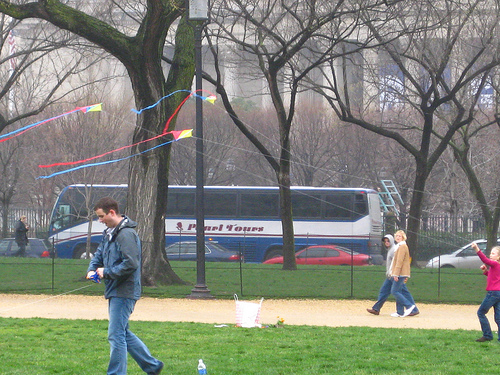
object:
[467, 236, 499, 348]
girl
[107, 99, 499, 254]
kite string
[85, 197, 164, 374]
man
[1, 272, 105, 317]
string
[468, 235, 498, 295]
pink shirt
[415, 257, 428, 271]
curb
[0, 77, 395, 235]
kite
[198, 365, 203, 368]
label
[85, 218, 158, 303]
black coat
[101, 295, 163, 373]
jean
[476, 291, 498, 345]
jean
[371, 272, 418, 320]
jean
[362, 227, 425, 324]
couple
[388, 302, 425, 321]
shoes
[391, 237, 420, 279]
shirt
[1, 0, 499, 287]
trees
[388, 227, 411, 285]
hoodie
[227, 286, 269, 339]
hand bag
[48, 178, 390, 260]
bus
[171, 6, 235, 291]
lamppost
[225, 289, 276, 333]
dog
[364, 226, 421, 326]
pedestrians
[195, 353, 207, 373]
bottle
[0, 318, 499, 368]
grass field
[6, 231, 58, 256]
hatchback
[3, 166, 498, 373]
people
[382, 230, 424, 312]
woman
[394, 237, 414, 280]
jacket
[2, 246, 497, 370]
grass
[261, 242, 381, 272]
car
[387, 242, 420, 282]
coat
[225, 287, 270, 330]
bag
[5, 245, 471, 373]
floor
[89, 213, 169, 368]
clothes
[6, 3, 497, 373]
park